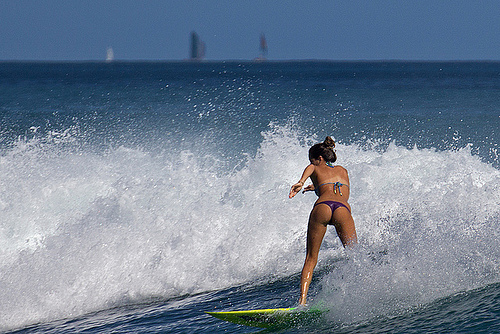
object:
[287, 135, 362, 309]
woman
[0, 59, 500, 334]
ocean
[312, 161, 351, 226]
bikini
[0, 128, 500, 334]
wave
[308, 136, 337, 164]
hair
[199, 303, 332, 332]
surfboard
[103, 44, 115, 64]
sail boat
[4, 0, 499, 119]
background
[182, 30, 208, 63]
sail boat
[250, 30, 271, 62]
sail boat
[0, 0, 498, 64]
sky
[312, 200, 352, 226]
bikini bottom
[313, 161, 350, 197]
bikini top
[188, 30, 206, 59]
sail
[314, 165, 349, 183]
tan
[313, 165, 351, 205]
back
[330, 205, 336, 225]
wedgie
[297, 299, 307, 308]
foot